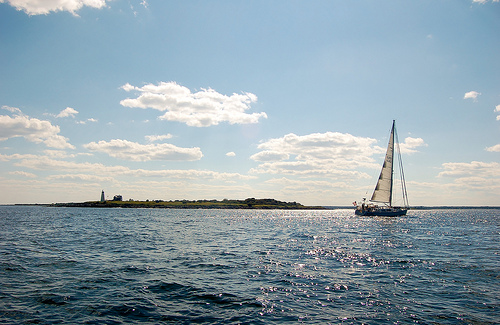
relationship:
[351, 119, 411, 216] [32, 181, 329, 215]
boat near island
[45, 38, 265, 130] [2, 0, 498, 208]
clouds sky in sky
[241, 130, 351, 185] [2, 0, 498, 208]
clouds sky in sky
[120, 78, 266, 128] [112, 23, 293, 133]
cloud in blue sky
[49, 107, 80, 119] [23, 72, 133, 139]
cloud in sky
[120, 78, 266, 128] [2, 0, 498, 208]
cloud in sky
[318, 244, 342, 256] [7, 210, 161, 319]
sunlight on water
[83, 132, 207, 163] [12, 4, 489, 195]
cloud in sky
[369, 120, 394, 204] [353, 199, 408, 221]
sail on a boat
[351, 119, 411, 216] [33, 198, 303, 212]
boat near land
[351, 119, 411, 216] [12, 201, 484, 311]
boat in water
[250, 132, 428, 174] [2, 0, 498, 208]
cloud in sky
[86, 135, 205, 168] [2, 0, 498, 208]
cloud in sky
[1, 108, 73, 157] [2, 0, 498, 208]
cloud in sky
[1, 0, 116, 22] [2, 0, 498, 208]
cloud in sky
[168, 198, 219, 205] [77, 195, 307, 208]
grass on island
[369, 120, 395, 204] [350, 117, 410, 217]
sail to sailboat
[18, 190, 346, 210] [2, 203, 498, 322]
island near water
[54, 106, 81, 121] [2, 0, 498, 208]
cloud in sky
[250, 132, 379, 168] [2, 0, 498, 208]
cloud in sky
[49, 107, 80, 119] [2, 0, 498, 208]
cloud in sky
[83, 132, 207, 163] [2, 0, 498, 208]
cloud in sky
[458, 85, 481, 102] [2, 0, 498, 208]
clouds in sky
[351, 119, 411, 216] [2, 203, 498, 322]
boat in water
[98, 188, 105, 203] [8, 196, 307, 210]
lighthouse on land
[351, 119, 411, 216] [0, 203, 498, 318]
boat on ocean